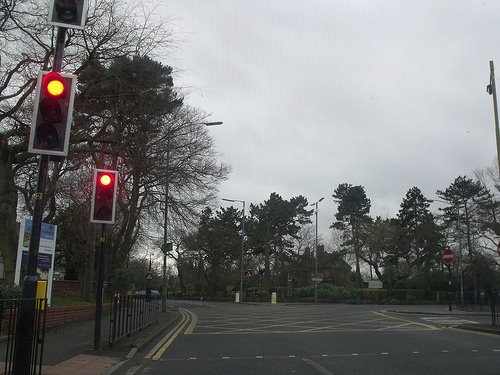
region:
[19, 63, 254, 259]
the traffic lights are on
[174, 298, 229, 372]
the lines are yellow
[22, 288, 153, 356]
the gate has an opening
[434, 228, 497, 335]
a caution sign is posted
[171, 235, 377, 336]
the leaves are green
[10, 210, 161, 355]
a sign is on the grass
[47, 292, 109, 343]
a brick wall by the sidewalk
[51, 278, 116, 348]
grass is by the brick wall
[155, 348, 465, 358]
dots are on the ground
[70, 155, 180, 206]
the light is red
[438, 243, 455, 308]
a red street sign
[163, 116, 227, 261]
a light on a pole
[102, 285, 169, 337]
a black fence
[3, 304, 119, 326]
a brick wall behind the sidewalk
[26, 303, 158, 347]
the sidewalk behind the fence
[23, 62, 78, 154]
a red stop light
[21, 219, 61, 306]
a white sign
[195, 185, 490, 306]
tall trees in the background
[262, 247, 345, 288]
a house behind the trees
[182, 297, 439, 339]
yellow lines on the street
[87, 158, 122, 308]
traffic light on a pole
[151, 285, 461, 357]
lines on the ground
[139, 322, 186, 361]
two parallel lines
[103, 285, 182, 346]
black fence along the sidewalk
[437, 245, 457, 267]
red and white sign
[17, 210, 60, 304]
sign on the grass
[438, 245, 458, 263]
do not enter sign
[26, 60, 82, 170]
traffic light shining red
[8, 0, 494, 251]
gray clouds in the sky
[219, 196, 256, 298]
light pole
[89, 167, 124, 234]
traffic light shining red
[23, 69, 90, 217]
traffic light on a pole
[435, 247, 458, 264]
no not enter sign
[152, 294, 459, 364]
lines painted on the ground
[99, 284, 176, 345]
black railing along the sidewalk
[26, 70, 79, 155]
row of three lights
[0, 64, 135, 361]
Metal pole with traffic signal lights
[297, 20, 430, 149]
Sky with clouds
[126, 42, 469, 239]
Lot of trees with green leaves and branches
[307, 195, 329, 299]
Metal pole with street light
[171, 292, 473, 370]
Road marked with yellow and white color line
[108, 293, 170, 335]
Steel with metal fencing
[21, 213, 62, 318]
Advertisement board near the tree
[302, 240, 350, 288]
Buildings near the road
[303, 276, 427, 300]
Small plants near the tree